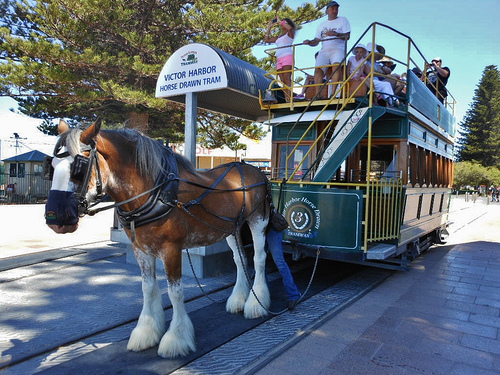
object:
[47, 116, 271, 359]
horse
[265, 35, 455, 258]
trolley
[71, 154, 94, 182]
blinders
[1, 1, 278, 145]
tree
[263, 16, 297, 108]
woman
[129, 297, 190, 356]
hooves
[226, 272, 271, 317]
hooves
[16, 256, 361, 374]
tracks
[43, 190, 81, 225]
mask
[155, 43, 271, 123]
shelter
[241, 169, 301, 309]
person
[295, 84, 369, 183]
stairway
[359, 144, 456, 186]
windows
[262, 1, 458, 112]
people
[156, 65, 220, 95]
letters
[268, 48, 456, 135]
top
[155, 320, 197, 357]
foot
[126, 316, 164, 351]
foot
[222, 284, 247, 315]
foot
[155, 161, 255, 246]
body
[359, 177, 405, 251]
door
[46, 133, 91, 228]
face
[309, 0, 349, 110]
tourist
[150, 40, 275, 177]
station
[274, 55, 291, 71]
shorts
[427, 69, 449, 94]
shirt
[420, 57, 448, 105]
man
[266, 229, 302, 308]
leg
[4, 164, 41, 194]
part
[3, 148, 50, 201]
building